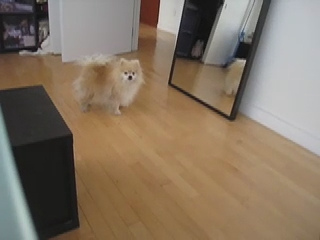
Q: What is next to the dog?
A: A mirror.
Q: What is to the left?
A: A black shelf.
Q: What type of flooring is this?
A: Wooden.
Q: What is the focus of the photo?
A: The dog.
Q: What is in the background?
A: A white door.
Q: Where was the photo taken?
A: In a bedroom.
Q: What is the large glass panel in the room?
A: A mirror.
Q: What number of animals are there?
A: One.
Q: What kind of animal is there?
A: A dog.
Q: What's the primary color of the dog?
A: Beige.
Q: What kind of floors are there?
A: Hardwood.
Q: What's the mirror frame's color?
A: Black.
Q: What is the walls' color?
A: White.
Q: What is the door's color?
A: White.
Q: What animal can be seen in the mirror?
A: The dog.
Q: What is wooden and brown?
A: The floor.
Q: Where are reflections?
A: In the mirror.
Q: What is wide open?
A: A door.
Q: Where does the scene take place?
A: In a room.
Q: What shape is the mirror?
A: Rectangular.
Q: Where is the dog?
A: The floor.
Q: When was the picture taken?
A: Daytime.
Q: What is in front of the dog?
A: A mirror.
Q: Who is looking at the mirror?
A: The dog.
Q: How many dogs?
A: 1.